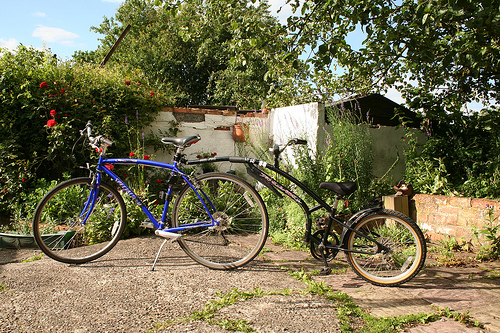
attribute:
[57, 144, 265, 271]
bike — bright blue, parked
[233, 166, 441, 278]
bike —  black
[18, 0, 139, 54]
sky — blue, white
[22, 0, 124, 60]
clouds — puffy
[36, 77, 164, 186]
flowers — red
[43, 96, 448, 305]
bikes —  two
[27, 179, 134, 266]
tire —   bike's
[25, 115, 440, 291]
bike —  together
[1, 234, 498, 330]
ground — cement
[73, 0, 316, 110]
trees —  green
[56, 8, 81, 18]
sky — blue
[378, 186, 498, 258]
wall —  brick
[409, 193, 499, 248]
wall —  stones,  red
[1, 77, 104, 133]
flowers — red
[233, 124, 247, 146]
pot —  Small,  terra cotta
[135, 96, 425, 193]
shed — White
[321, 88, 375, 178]
flowers — purple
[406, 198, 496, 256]
wall —  Small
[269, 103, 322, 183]
wall —  white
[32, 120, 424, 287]
bikes —   two,  parked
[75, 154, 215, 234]
body —  blue,   bike's